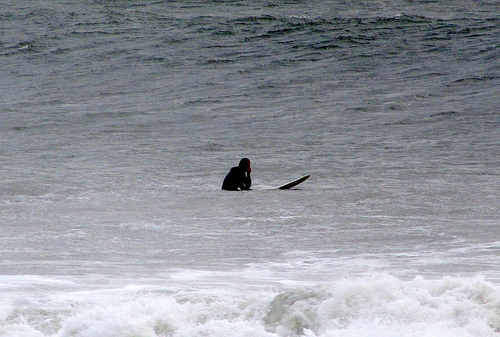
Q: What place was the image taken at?
A: It was taken at the ocean.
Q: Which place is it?
A: It is an ocean.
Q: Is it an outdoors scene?
A: Yes, it is outdoors.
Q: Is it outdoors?
A: Yes, it is outdoors.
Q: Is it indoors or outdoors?
A: It is outdoors.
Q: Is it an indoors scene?
A: No, it is outdoors.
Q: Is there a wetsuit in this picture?
A: Yes, there is a wetsuit.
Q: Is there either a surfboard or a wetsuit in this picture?
A: Yes, there is a wetsuit.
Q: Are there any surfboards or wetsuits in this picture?
A: Yes, there is a wetsuit.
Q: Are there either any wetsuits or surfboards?
A: Yes, there is a wetsuit.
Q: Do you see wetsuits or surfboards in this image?
A: Yes, there is a wetsuit.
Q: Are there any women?
A: No, there are no women.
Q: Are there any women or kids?
A: No, there are no women or kids.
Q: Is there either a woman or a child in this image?
A: No, there are no women or children.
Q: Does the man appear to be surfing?
A: Yes, the man is surfing.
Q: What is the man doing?
A: The man is surfing.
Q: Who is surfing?
A: The man is surfing.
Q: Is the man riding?
A: No, the man is surfing.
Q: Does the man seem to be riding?
A: No, the man is surfing.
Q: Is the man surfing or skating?
A: The man is surfing.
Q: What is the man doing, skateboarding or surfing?
A: The man is surfing.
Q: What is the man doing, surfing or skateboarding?
A: The man is surfing.